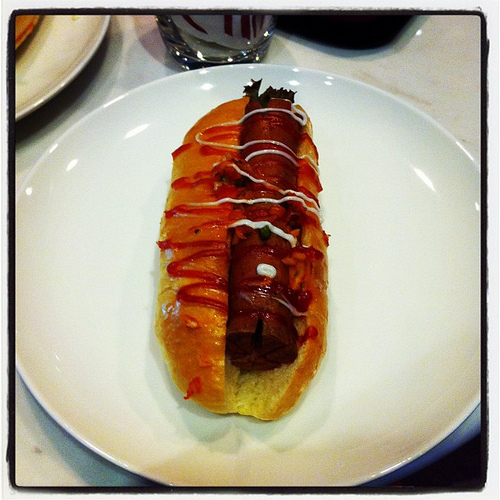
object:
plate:
[20, 61, 485, 488]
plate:
[15, 15, 112, 124]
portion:
[171, 82, 321, 177]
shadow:
[132, 18, 168, 73]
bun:
[151, 76, 335, 421]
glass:
[154, 10, 279, 62]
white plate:
[12, 65, 490, 487]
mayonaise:
[210, 103, 324, 236]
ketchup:
[156, 125, 329, 341]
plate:
[6, 61, 488, 500]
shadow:
[410, 427, 493, 495]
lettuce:
[234, 73, 307, 111]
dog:
[227, 91, 301, 370]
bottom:
[163, 36, 278, 70]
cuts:
[245, 310, 270, 370]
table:
[1, 0, 500, 495]